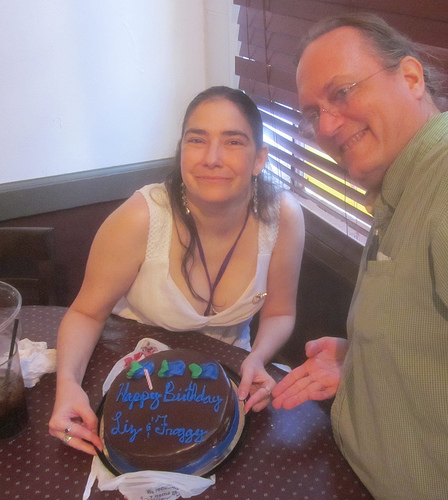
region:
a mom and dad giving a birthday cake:
[79, 15, 390, 335]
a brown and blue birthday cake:
[72, 334, 320, 470]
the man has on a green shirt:
[323, 187, 440, 434]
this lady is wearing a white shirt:
[136, 170, 283, 337]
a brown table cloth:
[250, 411, 344, 498]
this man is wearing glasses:
[289, 24, 421, 175]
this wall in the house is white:
[6, 10, 180, 158]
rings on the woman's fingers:
[43, 386, 85, 457]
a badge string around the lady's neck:
[175, 198, 258, 322]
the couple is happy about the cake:
[152, 24, 413, 210]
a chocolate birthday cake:
[101, 348, 239, 474]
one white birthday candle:
[143, 365, 155, 391]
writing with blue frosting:
[110, 381, 222, 446]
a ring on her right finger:
[63, 424, 72, 434]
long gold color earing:
[178, 180, 191, 220]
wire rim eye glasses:
[297, 59, 394, 133]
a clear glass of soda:
[0, 331, 26, 440]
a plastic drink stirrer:
[0, 314, 21, 379]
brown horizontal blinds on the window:
[231, 1, 297, 99]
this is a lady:
[104, 91, 294, 375]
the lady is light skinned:
[93, 237, 135, 279]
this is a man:
[293, 28, 446, 141]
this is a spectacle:
[306, 84, 354, 119]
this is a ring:
[57, 421, 71, 447]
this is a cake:
[103, 343, 220, 460]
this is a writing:
[121, 383, 214, 403]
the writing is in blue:
[113, 383, 178, 409]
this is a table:
[263, 405, 308, 467]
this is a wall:
[48, 20, 127, 96]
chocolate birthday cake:
[99, 345, 239, 478]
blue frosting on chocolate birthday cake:
[107, 380, 224, 449]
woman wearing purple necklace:
[174, 185, 258, 311]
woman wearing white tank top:
[120, 172, 284, 349]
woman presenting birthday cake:
[38, 80, 310, 458]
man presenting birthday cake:
[267, 9, 446, 496]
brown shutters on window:
[226, 1, 446, 267]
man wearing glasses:
[292, 58, 398, 127]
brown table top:
[1, 300, 378, 496]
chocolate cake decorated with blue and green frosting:
[100, 346, 247, 479]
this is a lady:
[89, 77, 297, 324]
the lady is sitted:
[89, 86, 295, 333]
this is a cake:
[103, 349, 229, 467]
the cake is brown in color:
[97, 353, 231, 461]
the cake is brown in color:
[183, 402, 206, 420]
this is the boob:
[222, 263, 267, 316]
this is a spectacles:
[303, 79, 354, 117]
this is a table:
[283, 418, 323, 491]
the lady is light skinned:
[105, 226, 144, 268]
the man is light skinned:
[380, 88, 409, 114]